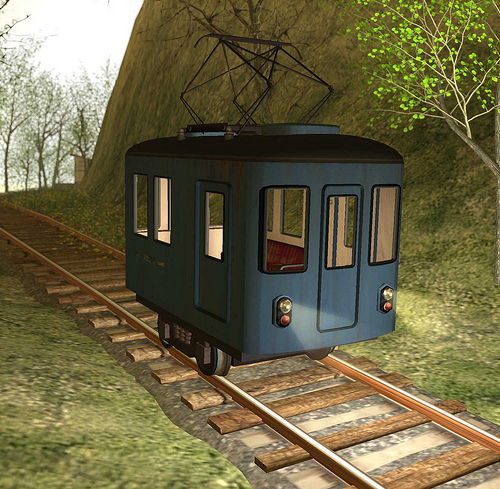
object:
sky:
[1, 0, 144, 193]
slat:
[252, 399, 468, 473]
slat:
[207, 371, 414, 435]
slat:
[180, 356, 378, 416]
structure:
[181, 32, 335, 124]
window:
[371, 186, 401, 263]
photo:
[0, 0, 500, 487]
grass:
[0, 252, 250, 489]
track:
[0, 183, 499, 433]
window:
[266, 188, 305, 271]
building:
[70, 153, 93, 186]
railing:
[279, 263, 304, 270]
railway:
[2, 197, 499, 487]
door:
[318, 183, 363, 333]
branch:
[463, 54, 498, 144]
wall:
[80, 0, 499, 306]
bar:
[205, 371, 413, 433]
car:
[123, 120, 405, 377]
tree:
[320, 0, 499, 187]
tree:
[0, 44, 42, 193]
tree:
[21, 75, 77, 190]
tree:
[42, 84, 84, 186]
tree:
[53, 80, 105, 182]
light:
[282, 300, 393, 373]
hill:
[79, 0, 500, 271]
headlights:
[271, 294, 296, 329]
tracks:
[2, 262, 255, 488]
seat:
[265, 237, 304, 271]